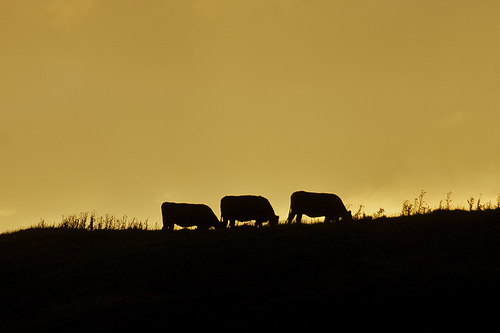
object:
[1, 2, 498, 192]
sky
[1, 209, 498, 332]
hill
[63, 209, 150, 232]
grass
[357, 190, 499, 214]
cloud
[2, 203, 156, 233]
cloud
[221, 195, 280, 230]
cow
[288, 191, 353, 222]
cow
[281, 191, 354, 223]
shadow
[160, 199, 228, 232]
cows